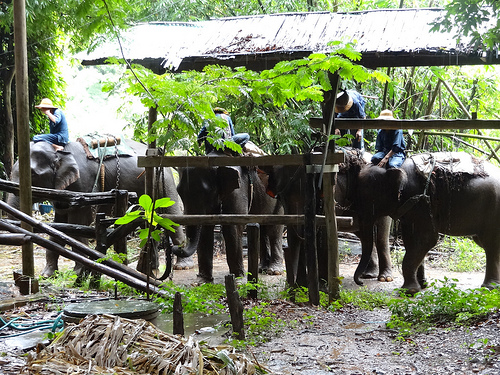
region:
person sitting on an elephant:
[33, 98, 70, 146]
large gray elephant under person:
[4, 132, 190, 279]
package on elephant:
[80, 130, 117, 148]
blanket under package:
[81, 136, 132, 160]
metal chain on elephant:
[103, 130, 123, 192]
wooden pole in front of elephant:
[12, 27, 34, 282]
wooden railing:
[137, 153, 344, 168]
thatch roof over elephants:
[85, 8, 499, 64]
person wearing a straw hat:
[36, 98, 56, 108]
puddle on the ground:
[151, 306, 220, 334]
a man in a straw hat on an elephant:
[27, 94, 84, 159]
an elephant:
[342, 144, 497, 299]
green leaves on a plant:
[106, 180, 185, 258]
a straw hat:
[370, 105, 400, 122]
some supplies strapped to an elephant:
[75, 128, 136, 174]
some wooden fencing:
[128, 142, 373, 241]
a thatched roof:
[125, 14, 456, 67]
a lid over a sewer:
[47, 283, 179, 350]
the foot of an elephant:
[370, 259, 405, 287]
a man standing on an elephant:
[322, 80, 378, 161]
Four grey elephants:
[6, 135, 499, 286]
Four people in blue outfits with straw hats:
[0, 87, 496, 168]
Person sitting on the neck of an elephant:
[0, 91, 177, 256]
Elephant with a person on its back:
[356, 110, 499, 297]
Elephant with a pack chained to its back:
[9, 133, 185, 269]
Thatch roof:
[92, 6, 499, 68]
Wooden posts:
[2, 143, 349, 310]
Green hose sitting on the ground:
[3, 305, 70, 342]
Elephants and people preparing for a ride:
[4, 84, 499, 301]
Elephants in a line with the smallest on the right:
[4, 131, 499, 292]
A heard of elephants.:
[11, 35, 487, 285]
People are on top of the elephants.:
[29, 82, 99, 178]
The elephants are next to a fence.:
[57, 134, 470, 273]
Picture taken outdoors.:
[64, 66, 406, 189]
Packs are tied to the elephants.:
[74, 111, 141, 194]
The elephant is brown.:
[439, 191, 480, 220]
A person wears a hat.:
[34, 98, 57, 114]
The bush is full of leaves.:
[116, 63, 328, 105]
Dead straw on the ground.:
[83, 318, 179, 359]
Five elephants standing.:
[19, 121, 496, 261]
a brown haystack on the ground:
[6, 280, 228, 374]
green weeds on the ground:
[62, 263, 499, 328]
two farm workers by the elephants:
[332, 79, 415, 165]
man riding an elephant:
[25, 86, 73, 153]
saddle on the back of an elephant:
[76, 126, 130, 175]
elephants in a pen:
[7, 95, 499, 295]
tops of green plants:
[3, 3, 498, 226]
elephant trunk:
[159, 195, 218, 264]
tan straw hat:
[32, 93, 59, 109]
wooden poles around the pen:
[2, 0, 364, 374]